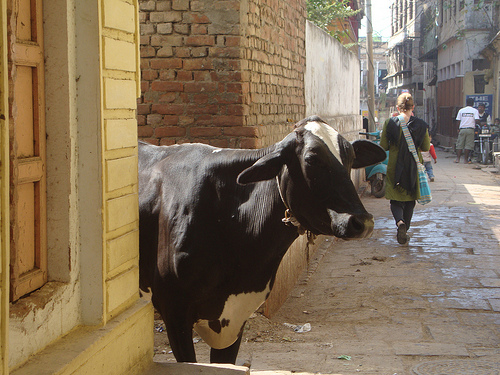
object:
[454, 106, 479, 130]
shirt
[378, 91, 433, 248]
lady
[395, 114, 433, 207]
bag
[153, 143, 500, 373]
ground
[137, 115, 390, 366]
cow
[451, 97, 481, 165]
man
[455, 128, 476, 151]
shorts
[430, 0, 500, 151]
building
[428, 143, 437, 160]
arm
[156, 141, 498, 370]
street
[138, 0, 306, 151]
wall